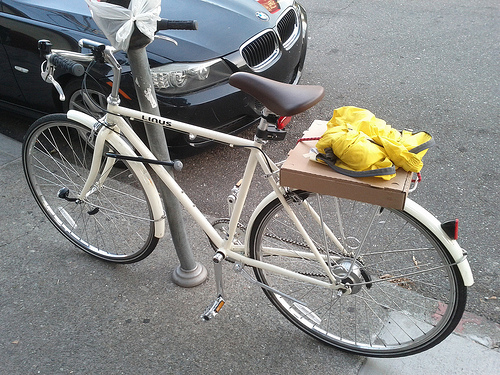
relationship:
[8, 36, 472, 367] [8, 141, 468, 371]
motorcycle in field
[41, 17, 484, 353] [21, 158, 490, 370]
bicycle on post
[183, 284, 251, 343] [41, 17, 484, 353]
pedal on a bicycle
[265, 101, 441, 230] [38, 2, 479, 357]
cardboard box on a bike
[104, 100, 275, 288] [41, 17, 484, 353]
frame of a bicycle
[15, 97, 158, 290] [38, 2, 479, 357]
tire on a bike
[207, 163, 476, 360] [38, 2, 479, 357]
tire on a bike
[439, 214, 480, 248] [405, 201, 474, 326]
reflector on back fender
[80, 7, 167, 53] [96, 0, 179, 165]
plastic around a pole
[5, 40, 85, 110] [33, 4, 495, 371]
handlebar grip on bicycle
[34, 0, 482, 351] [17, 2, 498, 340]
bicycle parking on street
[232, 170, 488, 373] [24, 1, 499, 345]
wheel of bike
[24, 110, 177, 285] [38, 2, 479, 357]
wheel of bike